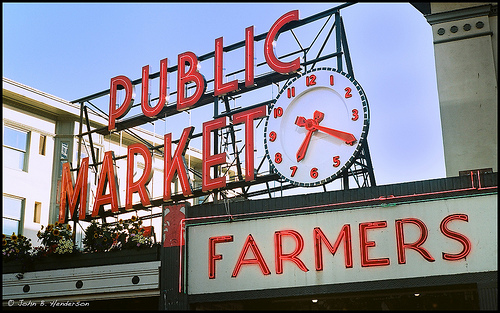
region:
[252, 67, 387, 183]
large red and white clock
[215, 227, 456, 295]
neon red and white sign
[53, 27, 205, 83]
sky is clear and blue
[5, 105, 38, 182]
top window of building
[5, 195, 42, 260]
bottom window in building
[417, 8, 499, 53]
decorative molding on building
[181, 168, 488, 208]
black frame around neon sign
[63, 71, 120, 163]
metal rack holding up neon letters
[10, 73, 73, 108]
trim on roof of building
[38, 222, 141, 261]
bushes in planters of building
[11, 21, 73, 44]
the sky is clear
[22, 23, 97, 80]
the sky is clear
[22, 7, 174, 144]
the sky is clear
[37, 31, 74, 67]
the sky is clear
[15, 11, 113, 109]
the sky is clear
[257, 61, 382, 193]
clock with red numbers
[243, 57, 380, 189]
red hour and minute hands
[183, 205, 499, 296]
red neon sign that says farmers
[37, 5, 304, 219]
public market in red neon letters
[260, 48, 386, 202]
clock that says seven twenty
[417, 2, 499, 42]
four dots under building cornice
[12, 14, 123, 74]
blue sky without clouds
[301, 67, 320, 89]
the number 12 in red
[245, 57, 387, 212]
white clock with red numbers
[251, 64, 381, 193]
white clock with red hour hand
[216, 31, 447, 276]
a clock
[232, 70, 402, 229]
a clock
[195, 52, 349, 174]
a clock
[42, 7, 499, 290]
A red sign on a metal frame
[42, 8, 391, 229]
A sign that says Public Market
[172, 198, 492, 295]
A sign with red letters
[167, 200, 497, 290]
A sign that says Farmers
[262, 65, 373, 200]
A white clock with red numbers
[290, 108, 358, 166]
Red hands on a white clock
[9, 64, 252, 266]
A building behind the sign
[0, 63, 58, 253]
Windows on a building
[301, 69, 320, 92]
The number twelve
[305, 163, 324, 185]
The number six